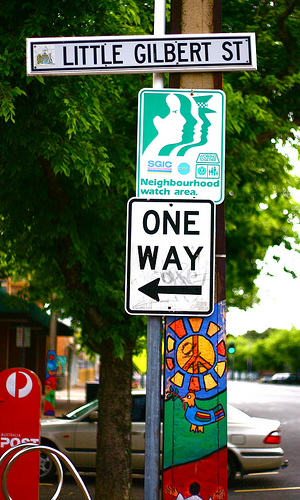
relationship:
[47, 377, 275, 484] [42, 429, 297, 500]
car in street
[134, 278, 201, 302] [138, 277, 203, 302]
arrow pointing arrow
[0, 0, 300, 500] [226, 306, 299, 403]
tree in background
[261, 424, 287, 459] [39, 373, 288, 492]
light of car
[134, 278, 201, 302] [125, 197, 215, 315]
arrow on sign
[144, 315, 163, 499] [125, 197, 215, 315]
pole supporting sign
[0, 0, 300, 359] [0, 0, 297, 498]
leaf on tree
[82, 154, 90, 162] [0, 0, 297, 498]
leaf on tree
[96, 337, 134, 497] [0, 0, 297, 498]
trunk of tree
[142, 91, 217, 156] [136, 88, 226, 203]
profile on sign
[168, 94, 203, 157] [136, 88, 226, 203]
profile on sign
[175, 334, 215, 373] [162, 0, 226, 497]
sign on pole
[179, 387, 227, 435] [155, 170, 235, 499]
bird on post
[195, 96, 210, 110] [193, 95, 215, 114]
brim on hat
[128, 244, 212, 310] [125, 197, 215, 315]
graffitti on sign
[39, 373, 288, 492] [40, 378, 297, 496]
car parked on street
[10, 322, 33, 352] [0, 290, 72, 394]
sign on side of building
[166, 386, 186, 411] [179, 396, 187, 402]
branch in mouth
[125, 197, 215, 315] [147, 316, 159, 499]
sign on pole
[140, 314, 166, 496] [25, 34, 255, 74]
pole for sign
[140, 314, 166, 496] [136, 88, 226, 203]
pole for sign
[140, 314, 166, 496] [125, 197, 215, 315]
pole for sign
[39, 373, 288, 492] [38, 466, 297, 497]
car in lot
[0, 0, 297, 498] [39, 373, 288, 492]
tree on side of car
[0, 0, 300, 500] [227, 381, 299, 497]
tree alongside street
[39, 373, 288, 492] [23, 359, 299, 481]
car parked in parking spot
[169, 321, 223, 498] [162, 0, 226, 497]
graffiti on pole